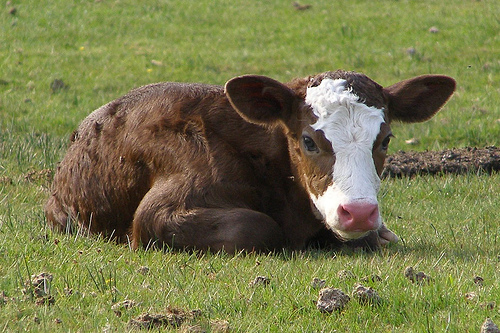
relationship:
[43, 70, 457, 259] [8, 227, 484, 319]
animal sitting on ground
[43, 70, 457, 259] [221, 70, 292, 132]
animal has ear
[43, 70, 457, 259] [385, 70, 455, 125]
animal has ear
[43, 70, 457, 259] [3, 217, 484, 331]
animal sitting in field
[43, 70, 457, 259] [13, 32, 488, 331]
animal sitting in field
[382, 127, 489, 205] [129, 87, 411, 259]
log behind cow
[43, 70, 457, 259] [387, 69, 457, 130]
animal has ear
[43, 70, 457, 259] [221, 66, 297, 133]
animal has ear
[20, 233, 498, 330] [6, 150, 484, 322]
rocks in grass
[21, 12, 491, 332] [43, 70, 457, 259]
grass behind animal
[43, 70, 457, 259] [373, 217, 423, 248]
animal has cow foot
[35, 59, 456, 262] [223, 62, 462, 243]
animal has head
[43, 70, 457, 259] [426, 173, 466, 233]
animal on grass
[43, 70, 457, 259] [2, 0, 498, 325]
animal on grass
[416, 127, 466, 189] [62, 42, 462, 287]
dirt on animal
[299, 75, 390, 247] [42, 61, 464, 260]
white part on cow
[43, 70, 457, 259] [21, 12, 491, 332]
animal lying on grass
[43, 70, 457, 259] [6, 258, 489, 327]
animal in gress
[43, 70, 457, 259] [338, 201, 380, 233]
animal has nose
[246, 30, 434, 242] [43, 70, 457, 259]
face on animal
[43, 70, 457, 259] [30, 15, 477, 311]
animal resting in field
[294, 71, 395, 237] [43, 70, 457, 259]
face on animal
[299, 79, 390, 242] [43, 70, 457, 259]
white part on animal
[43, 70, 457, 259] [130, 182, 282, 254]
animal has leg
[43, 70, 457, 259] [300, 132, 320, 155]
animal has eye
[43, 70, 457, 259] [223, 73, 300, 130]
animal has ear